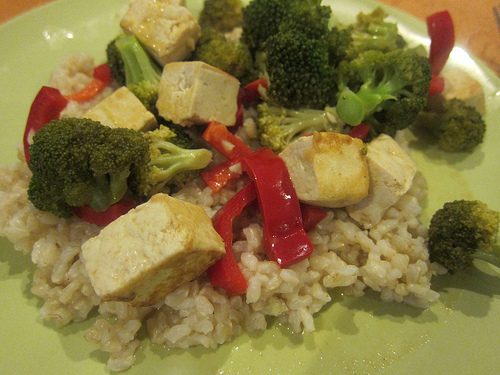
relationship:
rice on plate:
[0, 53, 448, 373] [14, 6, 499, 368]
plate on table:
[14, 6, 499, 368] [391, 0, 498, 75]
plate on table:
[14, 6, 499, 368] [1, 2, 42, 22]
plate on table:
[14, 6, 499, 368] [5, 4, 485, 62]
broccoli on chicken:
[27, 0, 500, 279] [97, 201, 213, 281]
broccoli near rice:
[407, 162, 499, 287] [355, 195, 431, 298]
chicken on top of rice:
[78, 0, 417, 310] [28, 148, 443, 363]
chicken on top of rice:
[284, 132, 369, 201] [28, 148, 443, 363]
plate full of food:
[14, 6, 499, 368] [2, 0, 499, 370]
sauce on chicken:
[113, 19, 181, 49] [78, 197, 225, 304]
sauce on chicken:
[113, 19, 181, 49] [276, 127, 369, 207]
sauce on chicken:
[113, 19, 181, 49] [154, 57, 269, 150]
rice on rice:
[0, 53, 448, 373] [100, 211, 433, 373]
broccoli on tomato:
[27, 0, 500, 279] [26, 77, 128, 222]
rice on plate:
[0, 50, 439, 373] [14, 6, 499, 368]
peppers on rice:
[204, 117, 326, 294] [318, 220, 427, 295]